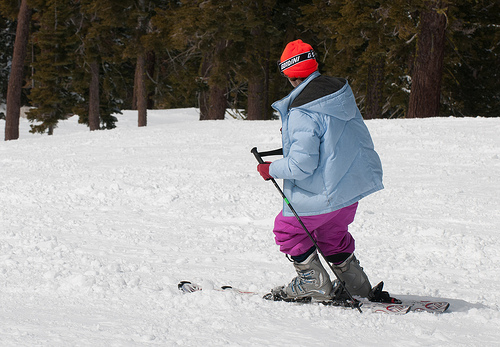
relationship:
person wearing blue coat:
[250, 39, 383, 300] [271, 70, 384, 217]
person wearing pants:
[250, 39, 383, 300] [270, 197, 362, 264]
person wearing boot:
[250, 39, 383, 300] [260, 249, 333, 303]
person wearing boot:
[250, 39, 383, 300] [324, 254, 384, 299]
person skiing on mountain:
[250, 39, 383, 300] [5, 108, 485, 340]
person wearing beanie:
[250, 39, 383, 300] [277, 39, 318, 78]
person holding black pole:
[250, 39, 383, 300] [250, 146, 363, 314]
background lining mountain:
[2, 1, 498, 141] [0, 108, 500, 347]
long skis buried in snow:
[177, 281, 449, 315] [15, 170, 145, 340]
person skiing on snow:
[250, 39, 383, 300] [43, 140, 177, 326]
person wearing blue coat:
[250, 39, 383, 300] [267, 72, 384, 217]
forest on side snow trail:
[3, 0, 480, 140] [7, 140, 480, 343]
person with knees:
[250, 39, 383, 300] [273, 202, 359, 256]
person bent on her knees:
[250, 39, 383, 300] [269, 209, 352, 259]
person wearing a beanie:
[250, 39, 383, 300] [277, 39, 318, 78]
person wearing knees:
[250, 39, 383, 300] [273, 202, 359, 256]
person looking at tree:
[250, 39, 383, 300] [23, 0, 76, 135]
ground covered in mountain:
[30, 130, 197, 345] [0, 108, 500, 347]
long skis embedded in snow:
[175, 277, 448, 320] [55, 211, 192, 343]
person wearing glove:
[250, 39, 383, 300] [257, 161, 272, 181]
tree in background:
[168, 0, 276, 121] [2, 1, 482, 116]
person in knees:
[250, 39, 383, 300] [273, 202, 359, 256]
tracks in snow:
[16, 174, 239, 304] [49, 126, 233, 176]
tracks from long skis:
[16, 174, 239, 304] [177, 281, 449, 315]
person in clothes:
[243, 33, 400, 312] [256, 9, 423, 331]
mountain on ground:
[0, 108, 500, 347] [0, 107, 500, 347]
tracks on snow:
[16, 174, 239, 304] [9, 116, 454, 343]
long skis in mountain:
[177, 281, 449, 315] [0, 108, 500, 347]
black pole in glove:
[250, 146, 363, 314] [257, 161, 272, 181]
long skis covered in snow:
[177, 281, 449, 315] [0, 103, 500, 343]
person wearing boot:
[250, 39, 383, 300] [271, 245, 346, 302]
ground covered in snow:
[0, 107, 500, 347] [0, 103, 500, 343]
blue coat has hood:
[271, 70, 384, 217] [289, 73, 359, 121]